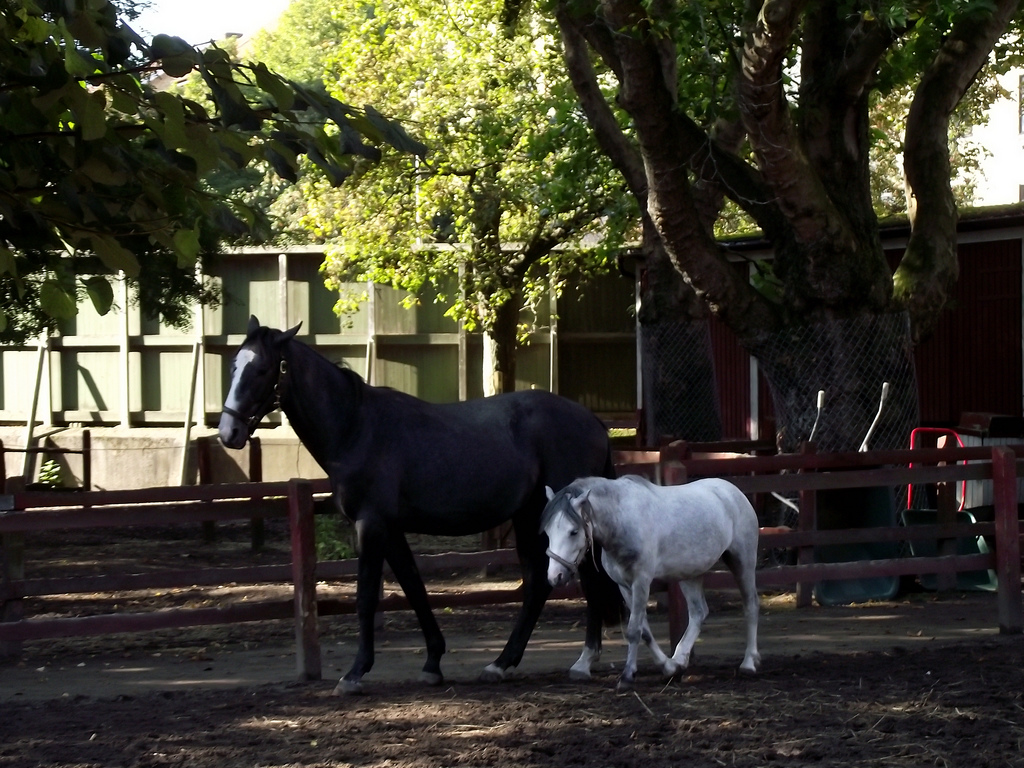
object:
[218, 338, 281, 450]
face